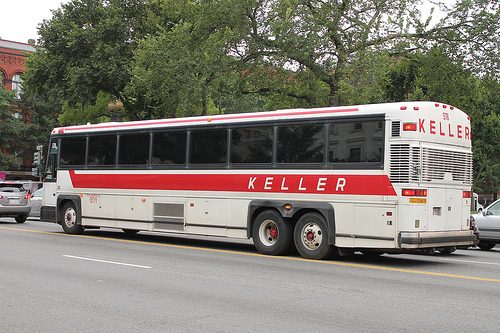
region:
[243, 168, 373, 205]
keller is written on the side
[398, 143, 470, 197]
vents aare on the bus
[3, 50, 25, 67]
the building is red in color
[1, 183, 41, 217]
the car is silver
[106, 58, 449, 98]
trees are in the background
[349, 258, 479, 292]
the line is yellow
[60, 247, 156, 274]
the line is white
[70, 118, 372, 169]
the windows are square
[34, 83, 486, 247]
white bus with a red stripe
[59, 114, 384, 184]
row of passengers windows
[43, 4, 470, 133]
large green trees on side of street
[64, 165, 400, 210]
red stripe with white lettering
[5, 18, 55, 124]
red brick building in the background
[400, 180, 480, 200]
red brake lights on bus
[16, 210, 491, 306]
yellow line painted down center of the street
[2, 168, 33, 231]
silver car in front of bus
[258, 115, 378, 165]
reflection of building on bus windows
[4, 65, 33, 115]
arched windows on brick building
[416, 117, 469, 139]
KELLER in red letters on the back of a bus.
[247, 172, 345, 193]
KELLER in white letters on the side of a bus.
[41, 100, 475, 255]
A white and red KELLER bus.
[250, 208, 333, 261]
Two black wheels under the white KELLER.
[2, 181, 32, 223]
Silver vehicle in front of a long bus.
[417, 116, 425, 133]
A red K in KELLER on the back of a bus.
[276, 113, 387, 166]
Back two windows over KELLER.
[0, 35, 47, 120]
Barely visible red brick building past the trees.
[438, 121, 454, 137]
Double L's in red letters on the back of the bus.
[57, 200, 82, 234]
A front black wheel of a bus.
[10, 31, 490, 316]
The bus is in the city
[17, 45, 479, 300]
The bus is carrying passengers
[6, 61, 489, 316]
The bus is on its route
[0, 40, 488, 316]
The bus is obeying the law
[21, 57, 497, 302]
The bus is carrying tourists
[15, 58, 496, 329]
The bus is owned by a company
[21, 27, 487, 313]
The bus is operated by the city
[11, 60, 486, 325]
The bus is passing a park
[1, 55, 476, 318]
The bus has many big windows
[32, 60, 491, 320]
The bus has a very powerful motor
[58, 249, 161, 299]
White line on pavement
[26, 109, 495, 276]
White and red bus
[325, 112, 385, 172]
Black reflective window on bus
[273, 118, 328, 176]
Black reflective window on bus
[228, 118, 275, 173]
Black reflective window on bus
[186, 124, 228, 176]
Black reflective window on bus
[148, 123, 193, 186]
Black reflective window on bus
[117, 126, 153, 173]
Black reflective window on bus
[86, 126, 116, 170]
Black reflective window on bus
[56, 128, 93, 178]
Black reflective window on bus